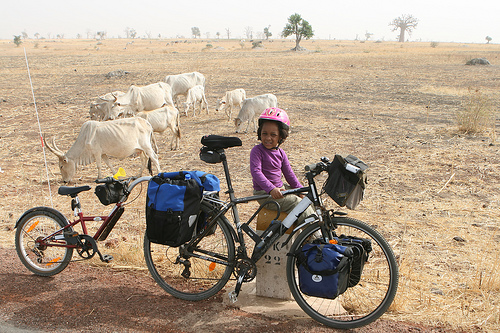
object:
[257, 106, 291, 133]
helmet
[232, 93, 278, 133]
cow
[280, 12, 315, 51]
tree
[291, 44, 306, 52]
trunk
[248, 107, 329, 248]
girl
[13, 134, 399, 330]
bike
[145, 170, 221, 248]
storage bag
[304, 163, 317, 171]
handle bars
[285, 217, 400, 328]
tire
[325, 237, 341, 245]
reflector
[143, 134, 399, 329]
bicycle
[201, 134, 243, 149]
seat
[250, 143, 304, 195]
shirt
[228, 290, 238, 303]
petal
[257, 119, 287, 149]
head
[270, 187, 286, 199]
hand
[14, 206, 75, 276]
wheel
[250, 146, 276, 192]
arm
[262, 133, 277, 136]
eyes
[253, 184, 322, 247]
leg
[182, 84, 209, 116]
goat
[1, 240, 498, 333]
dirt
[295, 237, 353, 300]
bag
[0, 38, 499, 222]
plain